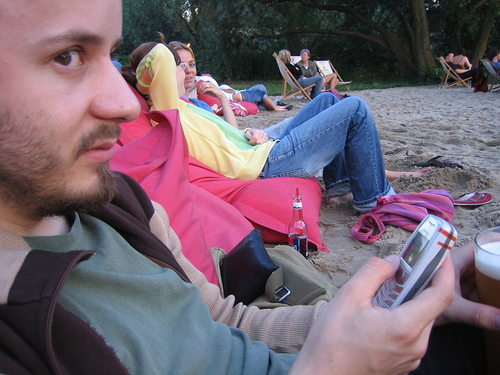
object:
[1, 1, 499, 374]
people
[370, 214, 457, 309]
cell phone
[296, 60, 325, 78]
shirt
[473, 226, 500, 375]
glass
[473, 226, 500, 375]
drinking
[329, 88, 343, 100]
flip flops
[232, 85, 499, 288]
beach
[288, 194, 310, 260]
bottle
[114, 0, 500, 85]
trees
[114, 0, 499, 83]
line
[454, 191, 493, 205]
sandal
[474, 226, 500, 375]
beer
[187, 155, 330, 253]
pillow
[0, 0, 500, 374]
man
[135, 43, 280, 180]
shirt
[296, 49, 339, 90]
person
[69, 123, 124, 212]
goatee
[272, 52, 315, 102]
chairs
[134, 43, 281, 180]
sweater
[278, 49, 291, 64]
hair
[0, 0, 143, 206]
face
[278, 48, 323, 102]
woman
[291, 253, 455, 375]
hand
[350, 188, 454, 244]
clothing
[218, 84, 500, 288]
ground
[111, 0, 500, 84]
forest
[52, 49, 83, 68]
eye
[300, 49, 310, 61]
head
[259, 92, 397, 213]
jeans